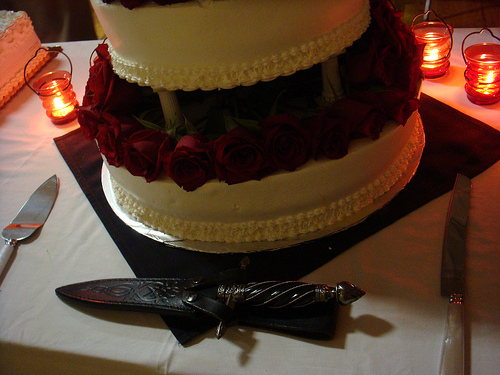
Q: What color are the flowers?
A: Red.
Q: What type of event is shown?
A: Wedding.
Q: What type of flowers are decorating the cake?
A: Roses.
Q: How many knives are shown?
A: Three.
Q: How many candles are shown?
A: Three.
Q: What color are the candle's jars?
A: Orange.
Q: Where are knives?
A: On the table.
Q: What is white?
A: Frosting on cake.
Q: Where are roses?
A: On the cake.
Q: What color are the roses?
A: Red.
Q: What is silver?
A: Knives.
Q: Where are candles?
A: On the table.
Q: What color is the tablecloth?
A: White.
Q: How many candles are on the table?
A: Three.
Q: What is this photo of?
A: The bottom layer of a cake.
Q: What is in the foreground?
A: A sheath covering the knife blade.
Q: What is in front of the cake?
A: A knife with ivory handle.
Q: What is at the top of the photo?
A: The top layer of the cake.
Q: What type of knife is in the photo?
A: A cake serving knife.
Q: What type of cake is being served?
A: A wedding cake with roses.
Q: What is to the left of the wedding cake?
A: A cake serving spatula.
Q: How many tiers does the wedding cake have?
A: 2.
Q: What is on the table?
A: The wedding cake.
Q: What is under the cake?
A: Black napkin.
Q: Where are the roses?
A: On the cake.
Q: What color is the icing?
A: White.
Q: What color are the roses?
A: Red.